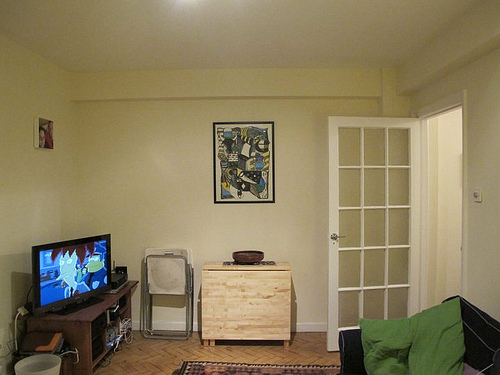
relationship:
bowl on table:
[235, 248, 265, 263] [199, 259, 290, 339]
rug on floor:
[171, 358, 342, 373] [87, 328, 339, 373]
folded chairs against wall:
[144, 249, 194, 334] [65, 65, 417, 336]